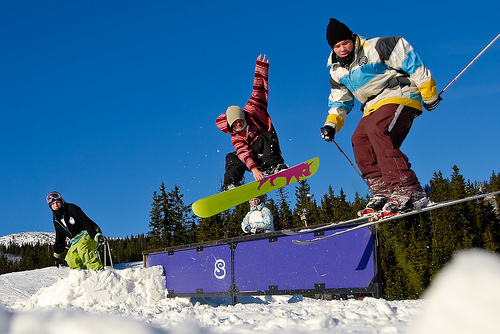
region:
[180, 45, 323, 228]
snow boarder jumping over snow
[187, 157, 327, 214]
green snow board with pink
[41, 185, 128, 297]
skier with goggles on head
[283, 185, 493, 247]
skis jumping through the air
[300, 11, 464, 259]
skier jumping a ramp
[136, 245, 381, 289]
blue fence around ramp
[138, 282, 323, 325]
snow with foot prints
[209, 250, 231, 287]
white logo with blue background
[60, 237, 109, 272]
lime green ski pants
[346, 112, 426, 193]
maroon ski pants with white stripe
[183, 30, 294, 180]
The shirt is red, pink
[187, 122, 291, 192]
He is wearing black pants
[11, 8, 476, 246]
It is sunny outside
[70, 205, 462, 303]
This is a blue gate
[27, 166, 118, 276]
He is looking at them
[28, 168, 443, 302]
There's trees in the background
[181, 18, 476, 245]
Both skiers are in the air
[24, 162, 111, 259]
His coat is black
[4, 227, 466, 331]
It has snowed on the mountain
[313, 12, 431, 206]
This man is looking down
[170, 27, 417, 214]
two men snowboarding together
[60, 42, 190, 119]
blue sky in the background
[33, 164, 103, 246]
man with goggles on head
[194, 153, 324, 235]
purple and gren snowboard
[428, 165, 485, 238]
green trees in distance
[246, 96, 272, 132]
purple and red sweater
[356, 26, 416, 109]
blue, gray and white jacket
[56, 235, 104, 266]
green pants on man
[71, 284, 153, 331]
white snow on ground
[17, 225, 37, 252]
mountain in the background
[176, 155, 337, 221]
Brightly colored snow board.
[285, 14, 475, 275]
Man in mid-air on skis.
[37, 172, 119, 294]
Person wearing lime green and black in the snow.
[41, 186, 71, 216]
Ski goggles on person's head.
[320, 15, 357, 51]
Black ski cap.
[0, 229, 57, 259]
Snow covered mountain with trees in front.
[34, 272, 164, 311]
Big mound of snow.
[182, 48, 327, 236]
Person on snow board.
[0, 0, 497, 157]
Blue sky.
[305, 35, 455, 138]
Striped ski jacket.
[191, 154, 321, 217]
A yellow and purple snowboard.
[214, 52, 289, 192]
A person on a yellow and purple snowboard.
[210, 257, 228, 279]
A white and blue S on a blue wall.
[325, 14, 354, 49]
A black toboggin on a guys head.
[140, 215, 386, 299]
A blue wall.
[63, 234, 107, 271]
Lime green snow pants on a guy.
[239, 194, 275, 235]
A person standing in a white snow coat.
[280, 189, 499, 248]
Skis on a person in the air.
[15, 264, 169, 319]
A small snow bank in front of a guy with lime green pants on.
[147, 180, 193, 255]
Three pine trees in a row to the left.